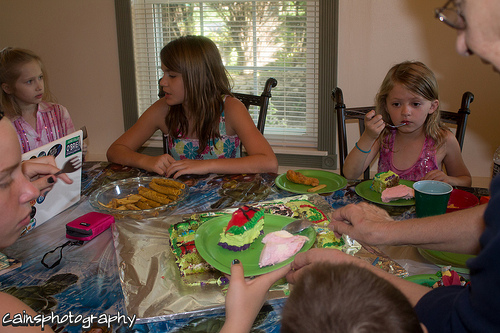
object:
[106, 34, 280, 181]
girl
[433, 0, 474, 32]
glasses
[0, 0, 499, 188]
wall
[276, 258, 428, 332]
head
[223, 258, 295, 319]
hand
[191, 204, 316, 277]
plate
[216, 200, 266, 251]
cake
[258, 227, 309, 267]
ice cream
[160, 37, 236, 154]
hair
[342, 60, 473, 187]
girl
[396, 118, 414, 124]
mouth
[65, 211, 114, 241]
bag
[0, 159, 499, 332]
table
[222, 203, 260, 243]
frosting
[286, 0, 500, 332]
man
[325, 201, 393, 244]
hand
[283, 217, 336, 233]
spoon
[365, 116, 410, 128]
fork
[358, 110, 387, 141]
hand